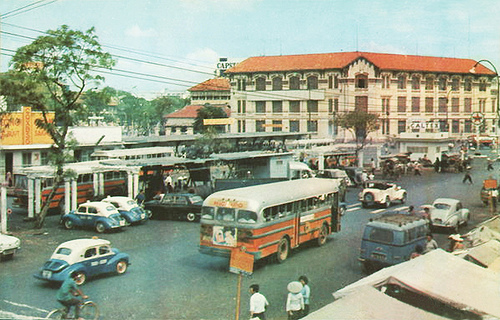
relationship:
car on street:
[33, 228, 142, 293] [1, 155, 498, 318]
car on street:
[33, 236, 131, 287] [1, 155, 498, 318]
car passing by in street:
[33, 236, 131, 287] [0, 168, 432, 318]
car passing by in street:
[33, 236, 131, 287] [1, 179, 421, 319]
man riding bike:
[56, 272, 88, 319] [40, 295, 104, 318]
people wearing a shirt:
[285, 280, 305, 319] [246, 292, 268, 315]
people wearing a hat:
[285, 280, 305, 319] [286, 280, 303, 293]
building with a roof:
[226, 50, 499, 166] [226, 51, 494, 77]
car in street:
[33, 236, 131, 287] [0, 220, 410, 316]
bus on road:
[192, 173, 339, 260] [174, 170, 484, 310]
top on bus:
[202, 176, 342, 210] [196, 173, 348, 268]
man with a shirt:
[246, 282, 269, 319] [249, 293, 268, 313]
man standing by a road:
[248, 284, 269, 320] [0, 215, 382, 318]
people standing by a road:
[285, 280, 304, 318] [0, 215, 382, 318]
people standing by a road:
[298, 273, 310, 301] [0, 215, 382, 318]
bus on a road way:
[192, 173, 339, 260] [0, 190, 423, 319]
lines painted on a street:
[343, 196, 437, 219] [1, 155, 498, 318]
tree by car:
[0, 20, 122, 230] [60, 199, 131, 232]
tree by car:
[0, 20, 122, 230] [101, 195, 149, 225]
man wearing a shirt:
[55, 270, 87, 318] [48, 282, 80, 304]